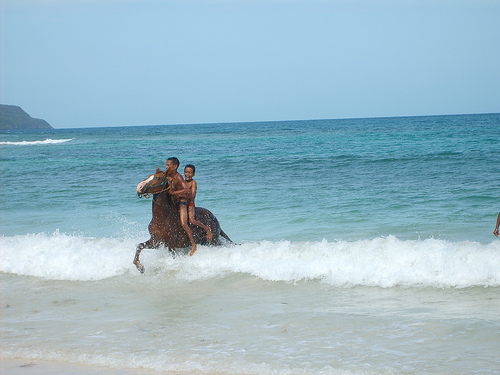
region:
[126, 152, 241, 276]
a glorious steed on the beach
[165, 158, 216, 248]
two shirtless kids riding a brown horse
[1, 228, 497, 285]
a white foamy wave crashing on the beach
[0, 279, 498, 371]
a little bit of water on the beach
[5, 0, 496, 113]
a clear blue sky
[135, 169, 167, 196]
a brown and white head horse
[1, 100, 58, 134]
a rocky mountain in the distance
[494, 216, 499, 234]
a persons arm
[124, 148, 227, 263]
two boys riding a brown horse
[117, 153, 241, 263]
two boys riding a horse on the beach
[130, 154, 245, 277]
two boys riding a horse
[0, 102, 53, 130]
a mountain in the distance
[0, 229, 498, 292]
a line of crashing surf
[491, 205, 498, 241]
a person's arm and hand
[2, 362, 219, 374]
a stretch of sand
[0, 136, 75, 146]
the foam of a crashing wave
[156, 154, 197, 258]
a young boy facing left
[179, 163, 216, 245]
a boy in bathing suit laughing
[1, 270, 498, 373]
a shallow spread of ocean water along the sand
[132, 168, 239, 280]
a brown horse with white face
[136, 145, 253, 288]
Two people riding a horse through water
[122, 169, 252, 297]
A brown horse running through the ocean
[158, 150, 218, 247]
Two kids on the back of a horse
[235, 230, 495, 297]
Thick white sea foam on the wave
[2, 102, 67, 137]
A large brown cliff in the distance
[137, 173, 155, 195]
Small white spot on the horse's head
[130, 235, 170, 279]
The horse is lifting up one of its front legs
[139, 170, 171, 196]
Reins on the horse's head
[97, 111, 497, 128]
The horizon far off in the distance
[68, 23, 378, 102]
A patch of clear blue sky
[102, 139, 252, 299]
boys riding a horse in the waves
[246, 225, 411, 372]
waves crashing up on the shore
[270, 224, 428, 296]
white foam on the waves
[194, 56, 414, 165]
clear blue sky above the ocean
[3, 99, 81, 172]
mountains on the side of the ocean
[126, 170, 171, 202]
white fur on the brown horse face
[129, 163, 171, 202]
bridle on the horse of the face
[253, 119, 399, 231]
clear blue clean water in the ocean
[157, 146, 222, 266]
boys riding the horse together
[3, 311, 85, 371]
shallow wave washing up on the sand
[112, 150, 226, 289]
brown horse in water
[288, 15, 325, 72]
white clouds in blue sky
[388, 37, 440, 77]
white clouds in blue sky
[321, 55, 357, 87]
white clouds in blue sky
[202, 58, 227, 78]
white clouds in blue sky